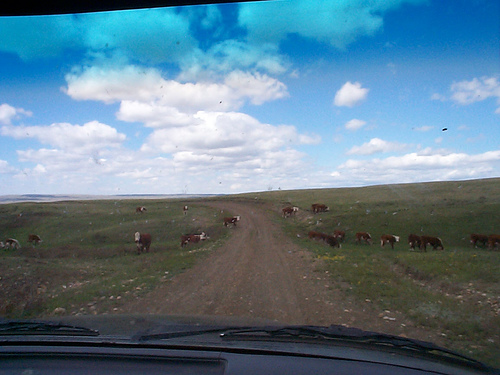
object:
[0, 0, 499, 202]
clouds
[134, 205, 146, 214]
cow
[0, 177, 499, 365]
field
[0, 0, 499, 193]
sky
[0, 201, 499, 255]
herd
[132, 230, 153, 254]
cattle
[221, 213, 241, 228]
cattle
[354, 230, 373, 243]
cattle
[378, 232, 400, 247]
cattle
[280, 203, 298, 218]
cattle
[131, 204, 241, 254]
cows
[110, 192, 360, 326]
dirt road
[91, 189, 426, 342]
road